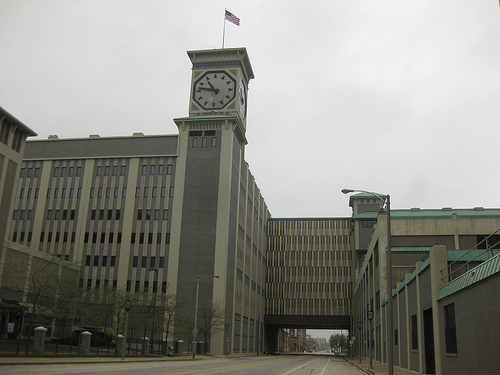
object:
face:
[192, 72, 236, 112]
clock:
[188, 49, 248, 131]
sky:
[2, 1, 500, 172]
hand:
[197, 86, 220, 93]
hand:
[207, 81, 218, 94]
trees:
[19, 256, 162, 354]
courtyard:
[4, 303, 186, 363]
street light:
[191, 273, 221, 361]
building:
[25, 139, 269, 357]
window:
[137, 209, 143, 220]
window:
[139, 232, 146, 246]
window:
[148, 233, 154, 245]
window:
[155, 209, 161, 220]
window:
[143, 186, 149, 197]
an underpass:
[265, 323, 353, 357]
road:
[4, 351, 361, 374]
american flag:
[224, 10, 242, 26]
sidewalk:
[1, 355, 203, 362]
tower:
[163, 118, 246, 355]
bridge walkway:
[264, 216, 357, 328]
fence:
[5, 331, 189, 356]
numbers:
[198, 73, 233, 110]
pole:
[221, 7, 227, 48]